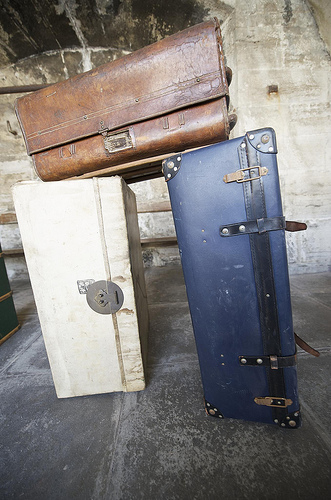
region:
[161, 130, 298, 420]
suitcase on the ground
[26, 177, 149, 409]
the suitcase on ground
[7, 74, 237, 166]
suitcase on the rgound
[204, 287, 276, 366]
the suitcase is blue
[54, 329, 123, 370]
he suitcase is white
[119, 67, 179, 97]
the suitcase is brown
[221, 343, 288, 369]
strap on the suitcase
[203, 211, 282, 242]
strap on the suitcase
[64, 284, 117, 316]
keyhole of the suitcase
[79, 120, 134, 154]
strap of the suitcase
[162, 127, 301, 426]
Blue suitcase on its side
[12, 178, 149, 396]
Scuffed white suitcase on its side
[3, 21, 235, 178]
Brown suitcase balanced on two others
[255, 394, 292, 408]
Strap on a blue suitcase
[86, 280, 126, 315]
Round metal clasp on a suitcase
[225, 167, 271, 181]
Metal clasp on a suitcase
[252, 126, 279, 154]
Reinforced corner on a blue suitcase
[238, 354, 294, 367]
Black strap on a blue suitcase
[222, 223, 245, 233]
Metal rivets on a suitcase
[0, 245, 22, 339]
Corner of a dark green suitcase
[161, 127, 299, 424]
Blue suitcase on the ground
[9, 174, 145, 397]
Tan suitcase on the ground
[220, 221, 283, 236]
Strap on blue suitcase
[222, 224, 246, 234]
Silver rivets on blue suitcase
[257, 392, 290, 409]
Rusty clasp on blue suitcase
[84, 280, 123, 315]
Round metal clasp on white suitcase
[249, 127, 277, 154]
Reinforced corner of blue suitcase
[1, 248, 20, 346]
Corner of dark green suitcase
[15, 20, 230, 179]
Brown leather suitcase on top of two others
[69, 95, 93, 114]
Scratch mark on suitcase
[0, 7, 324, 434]
looking down on several pieces of luggage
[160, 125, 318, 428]
this piece of luggage is blue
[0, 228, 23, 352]
this piece of luggage is green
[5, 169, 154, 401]
this piece of luggage is white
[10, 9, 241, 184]
this piece of luggage is brown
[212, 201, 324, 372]
the blue luggage has black leather straps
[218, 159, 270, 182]
the blue luggage has brass clasps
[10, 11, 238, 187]
the leather on the brown luggage is cracked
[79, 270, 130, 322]
the white luggage has only half a clasp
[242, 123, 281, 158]
the blue luggage has reinforced corners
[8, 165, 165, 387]
suitcase on the ground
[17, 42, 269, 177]
suitcase on the top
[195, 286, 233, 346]
the suitcase is blue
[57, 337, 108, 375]
the suitcase is white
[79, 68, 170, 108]
the suitcase is brown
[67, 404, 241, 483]
the ground is concrete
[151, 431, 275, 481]
the ground is dirty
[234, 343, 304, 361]
strap on the suitcase